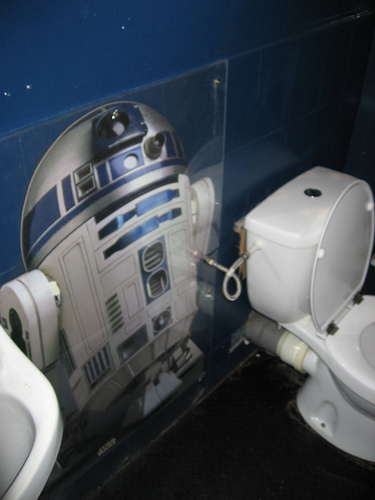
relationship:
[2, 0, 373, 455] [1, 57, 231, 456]
bathroom wall with poster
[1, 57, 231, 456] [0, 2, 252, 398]
poster covered in plastic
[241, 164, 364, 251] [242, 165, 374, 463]
basin cover on white toilet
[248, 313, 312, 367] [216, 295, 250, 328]
large pipe in wall